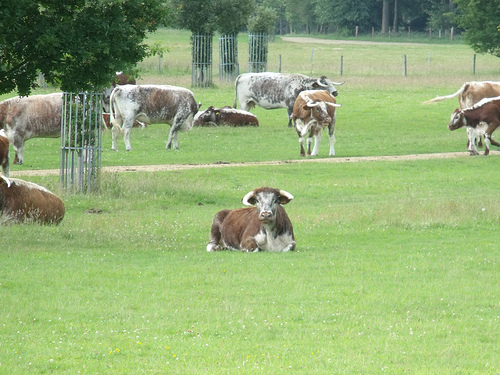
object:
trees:
[372, 5, 420, 42]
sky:
[371, 129, 422, 179]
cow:
[1, 87, 78, 168]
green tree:
[2, 0, 172, 195]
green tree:
[182, 0, 216, 87]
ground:
[0, 155, 500, 373]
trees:
[244, 5, 276, 75]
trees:
[160, 0, 222, 88]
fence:
[245, 29, 270, 74]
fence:
[218, 30, 240, 81]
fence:
[191, 31, 215, 88]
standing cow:
[446, 101, 499, 150]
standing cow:
[108, 80, 198, 155]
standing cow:
[227, 61, 343, 162]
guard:
[59, 90, 104, 197]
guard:
[192, 33, 216, 87]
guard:
[217, 30, 239, 85]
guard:
[247, 29, 269, 71]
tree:
[214, 0, 256, 81]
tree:
[1, 0, 172, 191]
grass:
[10, 84, 498, 374]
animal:
[446, 90, 499, 161]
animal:
[283, 80, 363, 156]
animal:
[231, 60, 344, 115]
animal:
[190, 104, 274, 136]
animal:
[106, 71, 207, 156]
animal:
[204, 184, 312, 259]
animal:
[2, 161, 69, 235]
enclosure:
[45, 83, 110, 189]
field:
[8, 71, 499, 371]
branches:
[36, 2, 143, 186]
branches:
[186, 0, 214, 69]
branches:
[218, 4, 242, 68]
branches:
[247, 2, 275, 64]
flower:
[70, 344, 136, 366]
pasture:
[2, 260, 494, 352]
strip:
[85, 148, 460, 180]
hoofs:
[250, 247, 289, 253]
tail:
[421, 81, 469, 103]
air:
[332, 9, 431, 111]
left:
[1, 2, 215, 372]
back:
[81, 82, 467, 242]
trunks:
[52, 103, 129, 303]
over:
[175, 80, 400, 174]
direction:
[12, 246, 448, 372]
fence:
[312, 50, 472, 128]